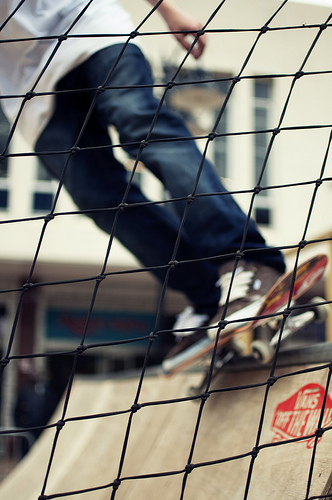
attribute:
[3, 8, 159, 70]
shirt — white